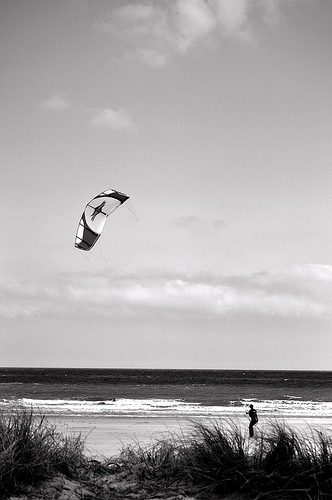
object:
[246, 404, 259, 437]
man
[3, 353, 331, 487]
beach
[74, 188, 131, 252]
kiteboarder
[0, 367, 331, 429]
sea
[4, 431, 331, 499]
plants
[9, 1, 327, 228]
sky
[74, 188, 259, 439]
kitesurfing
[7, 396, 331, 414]
waves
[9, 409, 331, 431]
shore line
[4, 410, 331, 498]
grass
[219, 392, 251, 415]
kite string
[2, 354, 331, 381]
horizon line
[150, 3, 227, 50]
cloud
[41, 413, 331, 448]
sand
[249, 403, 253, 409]
caps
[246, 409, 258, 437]
black